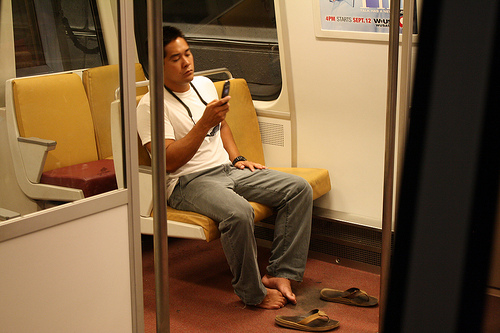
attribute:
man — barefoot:
[126, 41, 337, 321]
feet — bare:
[251, 270, 302, 315]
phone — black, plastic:
[213, 81, 234, 114]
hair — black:
[162, 25, 187, 58]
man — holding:
[119, 28, 336, 310]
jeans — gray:
[165, 161, 314, 303]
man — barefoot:
[148, 22, 313, 304]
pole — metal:
[121, 44, 185, 206]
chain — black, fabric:
[165, 90, 205, 111]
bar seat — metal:
[128, 64, 228, 85]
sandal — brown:
[272, 305, 341, 332]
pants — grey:
[179, 153, 321, 309]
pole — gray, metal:
[137, 0, 182, 332]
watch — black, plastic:
[224, 149, 269, 176]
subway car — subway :
[2, 4, 496, 331]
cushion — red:
[34, 151, 119, 192]